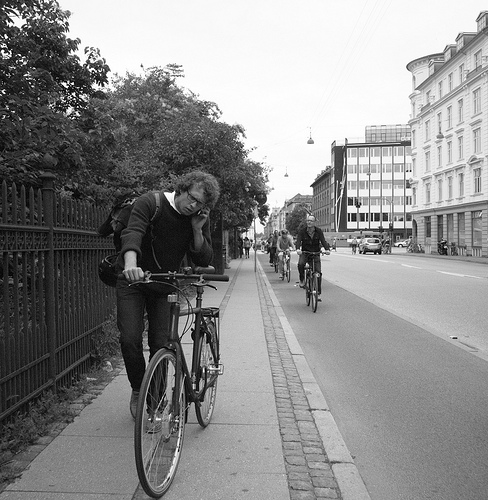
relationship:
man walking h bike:
[96, 169, 220, 438] [114, 273, 275, 459]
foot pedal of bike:
[201, 359, 227, 377] [122, 265, 231, 497]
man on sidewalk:
[96, 169, 220, 438] [222, 287, 273, 489]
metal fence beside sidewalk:
[1, 162, 127, 441] [39, 253, 345, 494]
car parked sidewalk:
[359, 236, 382, 255] [339, 242, 447, 306]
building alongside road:
[405, 8, 487, 258] [255, 239, 459, 496]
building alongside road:
[331, 136, 416, 244] [255, 239, 459, 496]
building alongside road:
[309, 165, 333, 234] [255, 239, 459, 496]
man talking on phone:
[96, 169, 220, 438] [106, 165, 221, 408]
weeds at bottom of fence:
[2, 308, 120, 451] [2, 152, 240, 428]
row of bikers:
[255, 221, 330, 307] [261, 223, 329, 312]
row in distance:
[255, 221, 330, 307] [224, 206, 395, 247]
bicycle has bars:
[117, 264, 231, 497] [142, 270, 234, 288]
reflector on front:
[166, 292, 180, 304] [137, 273, 218, 330]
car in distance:
[359, 236, 384, 258] [271, 209, 436, 279]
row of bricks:
[270, 326, 333, 488] [274, 343, 306, 421]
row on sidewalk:
[270, 326, 333, 488] [21, 244, 363, 498]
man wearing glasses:
[96, 169, 220, 438] [182, 189, 209, 210]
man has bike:
[96, 169, 220, 438] [133, 261, 224, 489]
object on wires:
[302, 137, 318, 149] [213, 3, 416, 196]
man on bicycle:
[108, 166, 221, 439] [121, 265, 232, 498]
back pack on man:
[104, 184, 163, 253] [108, 166, 221, 439]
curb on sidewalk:
[248, 258, 367, 491] [18, 242, 289, 495]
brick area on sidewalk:
[288, 453, 311, 492] [21, 244, 363, 498]